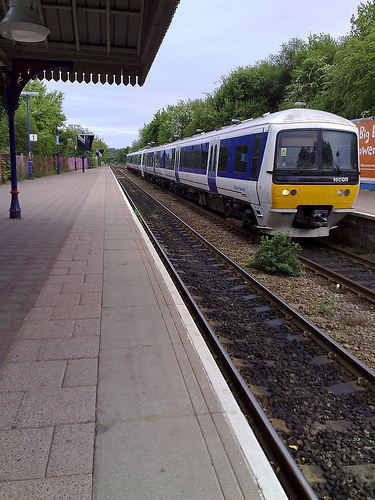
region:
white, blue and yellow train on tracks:
[127, 109, 362, 246]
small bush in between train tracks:
[250, 226, 302, 269]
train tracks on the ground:
[111, 164, 371, 497]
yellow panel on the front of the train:
[265, 175, 355, 211]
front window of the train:
[271, 124, 358, 184]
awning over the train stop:
[0, 2, 181, 83]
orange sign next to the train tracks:
[349, 111, 370, 180]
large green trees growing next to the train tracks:
[127, 0, 371, 151]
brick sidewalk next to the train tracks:
[0, 157, 267, 495]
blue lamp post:
[21, 90, 43, 180]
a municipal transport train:
[106, 103, 365, 243]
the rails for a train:
[85, 147, 373, 498]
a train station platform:
[0, 2, 316, 499]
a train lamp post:
[69, 127, 102, 172]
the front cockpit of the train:
[263, 103, 363, 242]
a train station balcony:
[3, 0, 193, 223]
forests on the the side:
[134, 27, 374, 145]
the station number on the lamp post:
[16, 85, 47, 181]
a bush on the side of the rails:
[245, 221, 309, 281]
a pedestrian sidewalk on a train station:
[1, 132, 304, 498]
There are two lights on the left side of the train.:
[276, 189, 300, 197]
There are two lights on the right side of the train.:
[338, 188, 351, 198]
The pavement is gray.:
[7, 370, 101, 499]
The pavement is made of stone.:
[8, 371, 90, 496]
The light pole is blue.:
[25, 93, 32, 179]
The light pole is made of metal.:
[22, 93, 34, 178]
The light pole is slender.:
[23, 91, 36, 177]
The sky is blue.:
[199, 16, 246, 54]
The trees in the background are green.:
[289, 31, 366, 94]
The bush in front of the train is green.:
[245, 228, 306, 274]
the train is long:
[94, 93, 349, 249]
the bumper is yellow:
[279, 181, 354, 215]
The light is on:
[266, 187, 302, 206]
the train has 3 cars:
[123, 148, 306, 193]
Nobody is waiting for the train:
[13, 116, 142, 494]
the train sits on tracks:
[121, 135, 313, 265]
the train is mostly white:
[109, 110, 311, 220]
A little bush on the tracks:
[234, 230, 311, 297]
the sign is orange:
[334, 119, 373, 166]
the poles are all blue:
[5, 132, 98, 193]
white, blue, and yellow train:
[135, 141, 342, 222]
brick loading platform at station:
[6, 157, 120, 451]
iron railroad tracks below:
[243, 283, 350, 446]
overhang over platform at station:
[9, 22, 174, 102]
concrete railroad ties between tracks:
[295, 362, 358, 453]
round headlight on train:
[269, 180, 297, 206]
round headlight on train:
[330, 184, 362, 206]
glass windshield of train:
[275, 127, 357, 177]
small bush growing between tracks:
[241, 235, 313, 273]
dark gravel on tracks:
[270, 405, 338, 466]